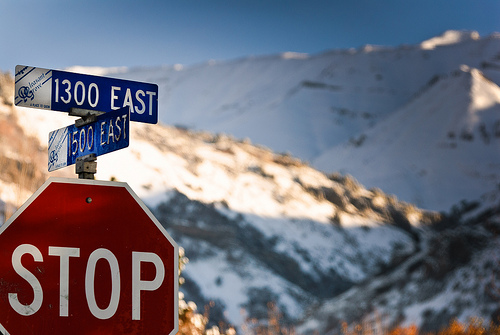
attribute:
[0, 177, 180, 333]
stop sign — red, white, octagonal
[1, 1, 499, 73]
sky — blue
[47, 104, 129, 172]
street sign — blue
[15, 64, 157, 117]
street sign — blue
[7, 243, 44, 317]
letter — white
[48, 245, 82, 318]
letter — white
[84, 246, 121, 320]
letter — white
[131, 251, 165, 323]
letter — white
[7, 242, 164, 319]
stop — white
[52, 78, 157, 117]
letters — white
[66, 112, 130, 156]
letters — white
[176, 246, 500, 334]
leaves — brown